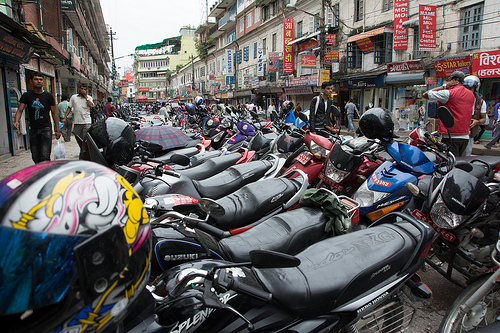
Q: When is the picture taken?
A: In the daytime.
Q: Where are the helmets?
A: On the bikes.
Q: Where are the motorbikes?
A: Parked on the street.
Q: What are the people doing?
A: Walking.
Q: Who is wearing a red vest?
A: A man on the right.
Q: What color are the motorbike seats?
A: Black.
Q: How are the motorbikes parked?
A: In rows.